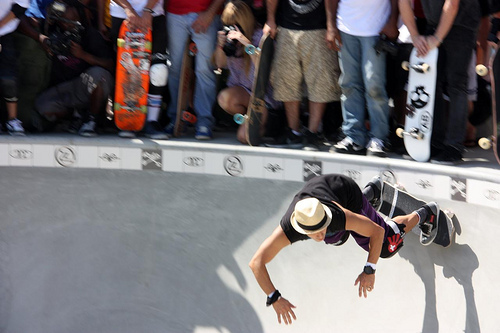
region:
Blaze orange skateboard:
[112, 16, 153, 138]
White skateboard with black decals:
[401, 39, 441, 159]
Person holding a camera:
[217, 4, 260, 112]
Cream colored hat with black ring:
[287, 195, 337, 237]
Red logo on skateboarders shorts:
[386, 227, 403, 260]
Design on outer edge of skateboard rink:
[23, 143, 322, 186]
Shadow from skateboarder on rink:
[400, 247, 491, 331]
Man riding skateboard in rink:
[244, 156, 462, 329]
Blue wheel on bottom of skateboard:
[233, 108, 248, 127]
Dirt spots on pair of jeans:
[341, 81, 386, 107]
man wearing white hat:
[250, 176, 457, 321]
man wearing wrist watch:
[250, 174, 456, 322]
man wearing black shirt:
[256, 170, 458, 330]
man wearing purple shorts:
[249, 173, 458, 327]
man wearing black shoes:
[251, 175, 454, 324]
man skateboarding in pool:
[7, 144, 494, 330]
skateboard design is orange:
[112, 12, 148, 129]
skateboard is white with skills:
[396, 35, 436, 161]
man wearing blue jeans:
[335, 0, 392, 160]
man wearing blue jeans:
[162, 10, 216, 137]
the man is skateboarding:
[199, 135, 467, 329]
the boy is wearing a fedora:
[283, 197, 367, 259]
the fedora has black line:
[273, 159, 367, 266]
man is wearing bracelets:
[234, 254, 370, 325]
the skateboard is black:
[356, 170, 468, 275]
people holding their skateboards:
[40, 46, 493, 179]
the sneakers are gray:
[353, 175, 475, 264]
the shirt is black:
[247, 161, 347, 233]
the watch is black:
[348, 253, 403, 297]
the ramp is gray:
[69, 183, 409, 325]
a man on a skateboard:
[248, 172, 458, 323]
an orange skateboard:
[115, 18, 149, 130]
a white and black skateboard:
[398, 37, 437, 159]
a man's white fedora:
[287, 198, 333, 234]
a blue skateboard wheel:
[232, 112, 243, 124]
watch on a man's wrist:
[362, 265, 373, 275]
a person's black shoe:
[5, 116, 24, 134]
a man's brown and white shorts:
[271, 28, 341, 101]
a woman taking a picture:
[216, 3, 268, 123]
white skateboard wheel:
[475, 63, 486, 75]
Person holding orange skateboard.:
[114, 18, 158, 173]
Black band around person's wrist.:
[258, 279, 288, 319]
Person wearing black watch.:
[361, 255, 381, 290]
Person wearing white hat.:
[286, 179, 339, 249]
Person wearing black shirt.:
[324, 180, 343, 208]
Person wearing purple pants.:
[356, 200, 396, 275]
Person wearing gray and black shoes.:
[408, 188, 449, 277]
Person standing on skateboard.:
[358, 172, 472, 307]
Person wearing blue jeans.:
[334, 45, 389, 131]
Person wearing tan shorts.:
[275, 21, 341, 101]